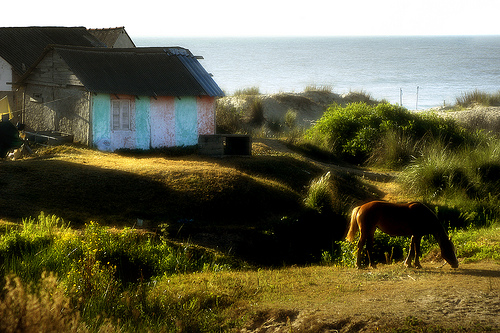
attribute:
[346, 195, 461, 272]
horse — grazing, brown, eating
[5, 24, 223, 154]
house — painted, blue, small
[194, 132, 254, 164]
stall — wooden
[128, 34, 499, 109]
water — distant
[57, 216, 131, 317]
flowers — wild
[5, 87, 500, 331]
field — grass, green colored, small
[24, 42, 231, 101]
roof — metal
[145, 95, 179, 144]
stripe — faded